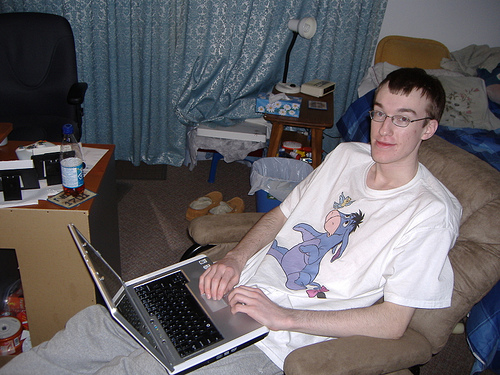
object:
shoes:
[204, 197, 245, 216]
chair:
[178, 134, 498, 374]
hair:
[371, 66, 446, 129]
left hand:
[226, 283, 280, 331]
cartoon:
[265, 192, 365, 303]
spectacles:
[366, 107, 431, 129]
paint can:
[0, 315, 28, 358]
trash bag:
[246, 155, 318, 204]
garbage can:
[245, 157, 315, 216]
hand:
[196, 260, 242, 302]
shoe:
[184, 187, 223, 223]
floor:
[114, 161, 255, 281]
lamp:
[274, 15, 317, 95]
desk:
[263, 90, 333, 169]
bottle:
[58, 124, 86, 199]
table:
[0, 143, 120, 348]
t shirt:
[226, 142, 461, 372]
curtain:
[0, 0, 387, 168]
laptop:
[66, 220, 271, 374]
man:
[0, 66, 462, 374]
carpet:
[114, 160, 253, 282]